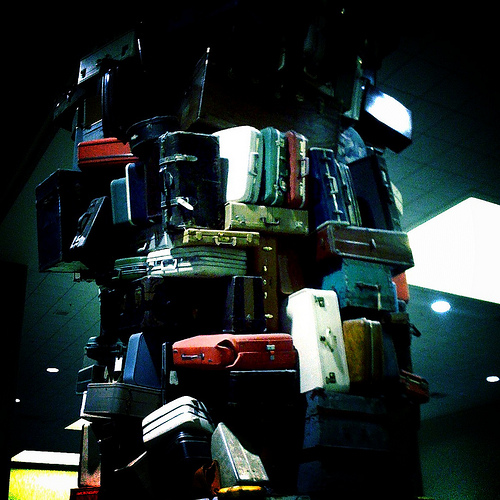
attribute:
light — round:
[425, 292, 452, 321]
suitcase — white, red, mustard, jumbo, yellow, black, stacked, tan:
[53, 34, 459, 475]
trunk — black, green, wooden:
[35, 161, 90, 264]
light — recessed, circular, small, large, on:
[366, 183, 495, 308]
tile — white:
[425, 64, 499, 136]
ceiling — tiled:
[387, 132, 499, 257]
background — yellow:
[389, 34, 490, 162]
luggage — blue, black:
[97, 298, 210, 397]